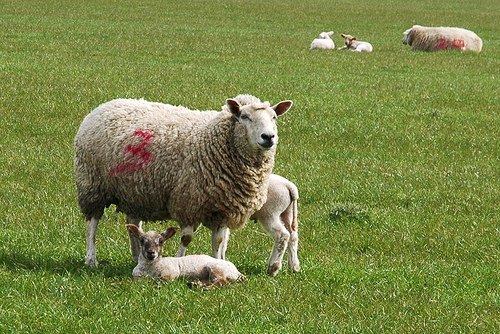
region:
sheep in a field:
[26, 15, 488, 302]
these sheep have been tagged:
[66, 2, 487, 199]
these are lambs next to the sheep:
[109, 177, 323, 325]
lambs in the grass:
[287, 22, 394, 64]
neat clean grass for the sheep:
[311, 77, 473, 229]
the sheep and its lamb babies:
[69, 79, 324, 294]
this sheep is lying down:
[393, 9, 490, 71]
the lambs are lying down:
[300, 19, 372, 58]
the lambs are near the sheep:
[109, 178, 340, 301]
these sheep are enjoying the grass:
[47, 29, 485, 283]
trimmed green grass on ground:
[4, 2, 497, 328]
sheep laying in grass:
[401, 23, 481, 53]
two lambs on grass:
[311, 29, 370, 51]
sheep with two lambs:
[71, 91, 303, 282]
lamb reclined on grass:
[127, 225, 242, 285]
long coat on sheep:
[74, 96, 274, 225]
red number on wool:
[111, 129, 153, 176]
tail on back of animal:
[290, 185, 299, 233]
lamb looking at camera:
[127, 224, 177, 260]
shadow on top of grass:
[1, 251, 261, 278]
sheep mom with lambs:
[54, 69, 329, 316]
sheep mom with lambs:
[302, 9, 490, 64]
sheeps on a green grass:
[5, 2, 497, 327]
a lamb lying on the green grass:
[115, 217, 258, 299]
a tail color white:
[281, 175, 302, 235]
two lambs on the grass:
[300, 20, 381, 58]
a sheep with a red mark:
[63, 78, 291, 243]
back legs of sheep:
[75, 210, 140, 267]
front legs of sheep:
[173, 215, 236, 253]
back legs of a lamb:
[264, 218, 302, 277]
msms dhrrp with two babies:
[68, 90, 300, 285]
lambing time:
[60, 21, 487, 325]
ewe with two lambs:
[73, 95, 301, 287]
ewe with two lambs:
[310, 23, 482, 57]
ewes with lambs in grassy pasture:
[3, 0, 497, 330]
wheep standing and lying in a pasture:
[10, 0, 497, 331]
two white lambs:
[309, 29, 373, 53]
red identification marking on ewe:
[112, 129, 153, 175]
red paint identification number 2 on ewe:
[434, 34, 448, 49]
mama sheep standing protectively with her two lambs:
[72, 92, 302, 286]